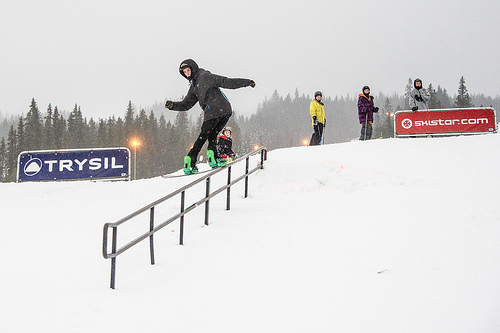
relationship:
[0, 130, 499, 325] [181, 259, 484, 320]
hill covered in snow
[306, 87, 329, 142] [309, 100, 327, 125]
person with jacket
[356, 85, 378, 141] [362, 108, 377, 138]
person standing with poles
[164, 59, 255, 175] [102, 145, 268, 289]
man snowboarding on banisters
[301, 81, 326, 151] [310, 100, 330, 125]
man wearing jacket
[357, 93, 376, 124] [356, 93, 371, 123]
jacket wearing jacket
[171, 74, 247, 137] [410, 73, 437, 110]
man wearing jacket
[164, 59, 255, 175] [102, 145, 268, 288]
man doing trick on railing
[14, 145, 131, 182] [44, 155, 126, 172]
sign with writing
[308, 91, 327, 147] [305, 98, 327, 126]
person wearing jacket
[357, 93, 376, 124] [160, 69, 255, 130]
jacket wearing jacket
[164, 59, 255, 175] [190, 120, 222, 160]
man wearing pants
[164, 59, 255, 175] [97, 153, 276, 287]
man doing trick on rail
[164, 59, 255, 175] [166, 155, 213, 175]
man using snow board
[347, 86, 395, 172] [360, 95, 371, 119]
person wearing jacket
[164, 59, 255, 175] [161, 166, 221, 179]
man on snow board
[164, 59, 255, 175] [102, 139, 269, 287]
man riding down rail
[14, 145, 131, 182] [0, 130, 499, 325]
sign on hill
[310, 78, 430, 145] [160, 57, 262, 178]
people watching snowboarder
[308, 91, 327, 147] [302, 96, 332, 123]
person standing in jacket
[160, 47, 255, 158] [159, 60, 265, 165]
hood on person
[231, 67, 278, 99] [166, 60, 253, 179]
gloves on person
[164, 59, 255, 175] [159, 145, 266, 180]
man on snowboard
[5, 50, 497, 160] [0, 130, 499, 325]
forest on top of hill